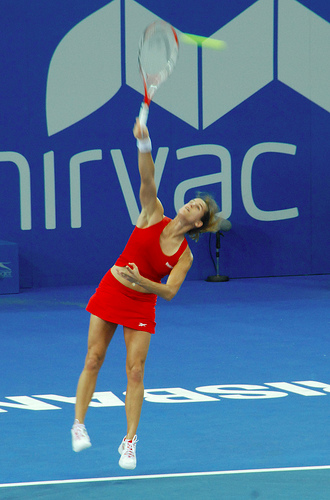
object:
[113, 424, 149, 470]
feet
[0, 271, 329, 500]
ground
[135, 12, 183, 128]
racquet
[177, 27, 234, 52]
ball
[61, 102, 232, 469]
woman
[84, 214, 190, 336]
outfit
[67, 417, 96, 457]
shoes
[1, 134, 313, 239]
words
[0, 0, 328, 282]
wall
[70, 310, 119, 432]
legs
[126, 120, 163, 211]
arm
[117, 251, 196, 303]
arm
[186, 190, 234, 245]
hair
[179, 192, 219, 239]
head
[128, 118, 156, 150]
hand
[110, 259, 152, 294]
midriff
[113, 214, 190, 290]
shirt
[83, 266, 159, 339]
skirt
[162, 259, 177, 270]
symbol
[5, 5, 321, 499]
tennis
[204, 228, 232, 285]
stand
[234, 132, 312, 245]
letters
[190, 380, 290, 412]
letters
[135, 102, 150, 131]
handle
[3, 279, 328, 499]
court